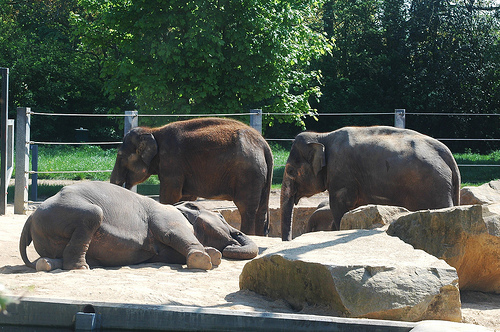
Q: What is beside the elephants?
A: Rock.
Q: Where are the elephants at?
A: Zoo.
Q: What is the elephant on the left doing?
A: Laying.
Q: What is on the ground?
A: Dust.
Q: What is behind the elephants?
A: Fence.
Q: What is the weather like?
A: Sunny.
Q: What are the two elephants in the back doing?
A: Standing.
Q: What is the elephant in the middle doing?
A: Laying down.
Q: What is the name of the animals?
A: Elephants.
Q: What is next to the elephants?
A: Rocks.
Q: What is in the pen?
A: Elephants and rocks.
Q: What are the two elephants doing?
A: Standing.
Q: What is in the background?
A: Trees.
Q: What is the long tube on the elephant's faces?
A: A trunk.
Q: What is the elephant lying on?
A: Dirt.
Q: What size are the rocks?
A: Very large.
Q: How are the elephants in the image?
A: Heavy.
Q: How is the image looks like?
A: Sunny.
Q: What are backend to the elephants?
A: Trees.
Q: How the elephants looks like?
A: Tired.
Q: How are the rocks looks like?
A: Big.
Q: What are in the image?
A: Elephants.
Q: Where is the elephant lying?
A: On ground.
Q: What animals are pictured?
A: Elephants.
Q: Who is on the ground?
A: An elephant.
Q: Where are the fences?
A: Around the elephants.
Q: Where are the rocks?
A: In the elephant pen.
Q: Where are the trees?
A: On the outside of the pen.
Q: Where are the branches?
A: On the trees.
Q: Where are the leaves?
A: On the trees.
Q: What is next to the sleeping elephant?
A: Big rocks.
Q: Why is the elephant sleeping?
A: It's tired.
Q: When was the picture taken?
A: Daytime.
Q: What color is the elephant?
A: Brown.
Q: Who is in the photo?
A: No one.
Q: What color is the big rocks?
A: Brown.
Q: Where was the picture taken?
A: At a zoo.